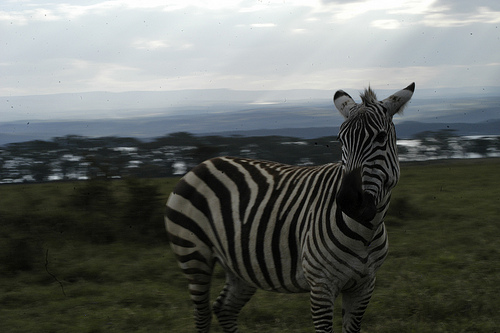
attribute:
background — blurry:
[2, 0, 497, 184]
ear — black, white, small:
[329, 87, 356, 119]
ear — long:
[383, 81, 418, 114]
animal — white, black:
[142, 65, 401, 328]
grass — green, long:
[56, 244, 148, 331]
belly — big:
[196, 222, 421, 279]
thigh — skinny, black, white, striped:
[167, 251, 224, 305]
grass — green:
[100, 268, 139, 299]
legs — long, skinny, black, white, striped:
[180, 281, 259, 328]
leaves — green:
[136, 188, 151, 215]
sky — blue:
[14, 18, 475, 71]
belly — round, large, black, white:
[208, 197, 290, 327]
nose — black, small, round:
[333, 182, 373, 219]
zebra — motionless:
[162, 82, 414, 330]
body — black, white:
[165, 155, 389, 290]